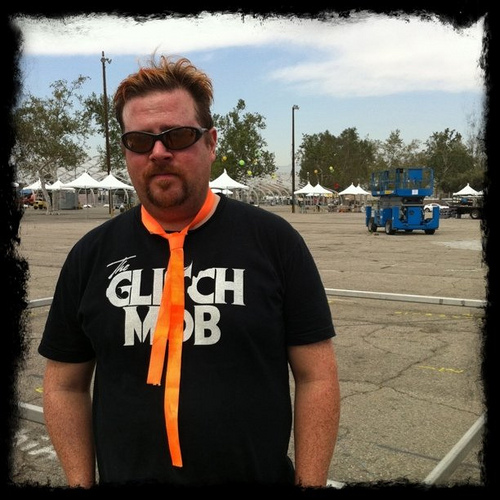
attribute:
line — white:
[329, 287, 484, 312]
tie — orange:
[150, 238, 186, 468]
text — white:
[102, 253, 247, 347]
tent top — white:
[207, 167, 258, 191]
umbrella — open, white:
[297, 181, 331, 198]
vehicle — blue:
[364, 167, 439, 232]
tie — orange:
[120, 192, 230, 477]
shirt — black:
[82, 200, 296, 290]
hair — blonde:
[107, 65, 208, 109]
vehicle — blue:
[362, 166, 439, 240]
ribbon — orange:
[138, 189, 223, 470]